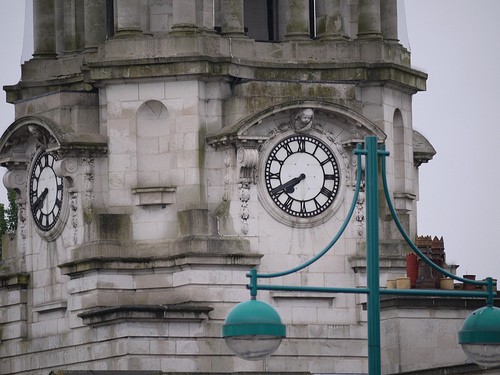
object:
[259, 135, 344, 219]
clock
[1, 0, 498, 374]
building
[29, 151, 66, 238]
clock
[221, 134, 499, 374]
light fixture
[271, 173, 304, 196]
hands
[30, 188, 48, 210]
hands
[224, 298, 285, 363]
light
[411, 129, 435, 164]
overhang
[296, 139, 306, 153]
number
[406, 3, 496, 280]
sky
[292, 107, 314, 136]
angel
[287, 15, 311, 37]
moss